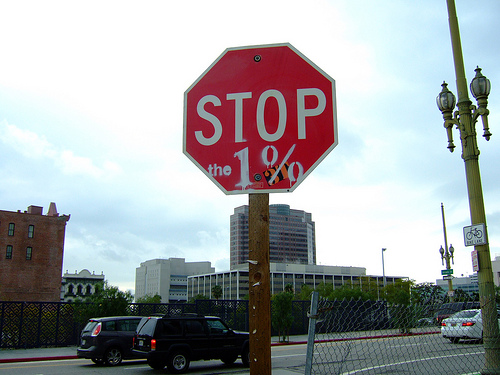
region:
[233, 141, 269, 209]
the number is white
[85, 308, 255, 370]
the cars on the road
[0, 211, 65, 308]
the building is brick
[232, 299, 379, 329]
the fence is black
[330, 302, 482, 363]
the gate is silver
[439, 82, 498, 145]
the lamps are vintage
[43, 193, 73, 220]
stack on top of building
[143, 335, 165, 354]
orange light at side of car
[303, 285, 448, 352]
gray chain link fence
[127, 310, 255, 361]
van driving on the street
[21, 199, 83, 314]
brown building on the side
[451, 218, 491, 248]
small white sign on pole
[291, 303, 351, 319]
brackets on gray fence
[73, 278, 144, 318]
green trees beside the black fence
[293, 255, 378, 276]
top of silver building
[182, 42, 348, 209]
this is a sign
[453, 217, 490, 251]
this is a sign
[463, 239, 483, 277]
this is a sign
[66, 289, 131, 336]
this is a tree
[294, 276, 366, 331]
this is a tree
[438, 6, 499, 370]
this is a post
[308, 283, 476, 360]
this is a mesh fense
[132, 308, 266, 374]
this is a car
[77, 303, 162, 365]
this is a car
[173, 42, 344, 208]
this is a sign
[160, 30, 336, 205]
this is a stop sign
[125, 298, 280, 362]
this is a car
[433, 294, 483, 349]
this is a car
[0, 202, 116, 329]
this is a building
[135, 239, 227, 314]
this is a building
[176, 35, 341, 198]
A red and white Stop sign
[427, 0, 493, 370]
A tall street lamp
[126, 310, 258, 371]
The side of a black jeep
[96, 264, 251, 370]
a black car on the road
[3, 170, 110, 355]
a brown building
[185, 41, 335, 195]
red and white sign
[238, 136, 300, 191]
grafitti on the sign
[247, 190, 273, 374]
the post is wood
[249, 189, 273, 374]
the post is brown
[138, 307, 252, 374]
a vehicle is driving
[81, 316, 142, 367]
the suv is blue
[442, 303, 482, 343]
the car is white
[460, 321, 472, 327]
the light is red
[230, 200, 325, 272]
the building is large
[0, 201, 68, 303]
building made of bricks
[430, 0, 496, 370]
A tall pole with two lamps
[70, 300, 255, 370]
Two vehicles side by side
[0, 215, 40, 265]
Four windows on a building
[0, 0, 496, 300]
The sky appears cloudy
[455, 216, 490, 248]
Picture of a bicycle on white sign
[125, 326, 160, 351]
Two rear vehicle lights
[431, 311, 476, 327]
Two red rear lights are turned on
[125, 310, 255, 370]
A jeep is black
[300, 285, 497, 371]
A gray iron fence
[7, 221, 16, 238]
window on brick red building